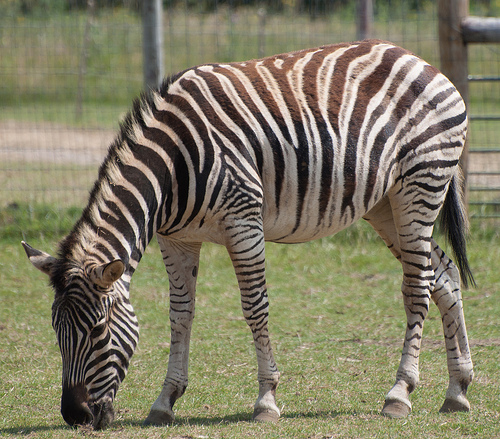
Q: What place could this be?
A: It is a zoo.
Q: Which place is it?
A: It is a zoo.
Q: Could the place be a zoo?
A: Yes, it is a zoo.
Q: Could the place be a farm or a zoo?
A: It is a zoo.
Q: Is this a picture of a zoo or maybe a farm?
A: It is showing a zoo.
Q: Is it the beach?
A: No, it is the zoo.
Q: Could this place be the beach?
A: No, it is the zoo.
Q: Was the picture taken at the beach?
A: No, the picture was taken in the zoo.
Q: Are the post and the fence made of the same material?
A: No, the post is made of wood and the fence is made of metal.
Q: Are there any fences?
A: Yes, there is a fence.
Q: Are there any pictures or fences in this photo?
A: Yes, there is a fence.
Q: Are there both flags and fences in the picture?
A: No, there is a fence but no flags.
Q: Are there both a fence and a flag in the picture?
A: No, there is a fence but no flags.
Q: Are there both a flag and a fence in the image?
A: No, there is a fence but no flags.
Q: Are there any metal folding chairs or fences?
A: Yes, there is a metal fence.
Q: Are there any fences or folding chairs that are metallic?
A: Yes, the fence is metallic.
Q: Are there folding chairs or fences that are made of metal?
A: Yes, the fence is made of metal.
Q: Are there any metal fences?
A: Yes, there is a metal fence.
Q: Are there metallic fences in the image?
A: Yes, there is a metal fence.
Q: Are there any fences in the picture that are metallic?
A: Yes, there is a fence that is metallic.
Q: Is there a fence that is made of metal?
A: Yes, there is a fence that is made of metal.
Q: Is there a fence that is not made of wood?
A: Yes, there is a fence that is made of metal.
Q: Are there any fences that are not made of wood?
A: Yes, there is a fence that is made of metal.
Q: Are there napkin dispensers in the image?
A: No, there are no napkin dispensers.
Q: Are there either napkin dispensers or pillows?
A: No, there are no napkin dispensers or pillows.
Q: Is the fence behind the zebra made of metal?
A: Yes, the fence is made of metal.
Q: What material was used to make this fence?
A: The fence is made of metal.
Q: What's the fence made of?
A: The fence is made of metal.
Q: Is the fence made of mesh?
A: No, the fence is made of metal.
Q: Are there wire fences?
A: No, there is a fence but it is made of metal.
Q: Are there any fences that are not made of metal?
A: No, there is a fence but it is made of metal.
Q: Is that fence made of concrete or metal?
A: The fence is made of metal.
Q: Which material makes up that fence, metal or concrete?
A: The fence is made of metal.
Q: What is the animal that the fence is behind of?
A: The animal is a zebra.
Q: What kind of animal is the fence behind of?
A: The fence is behind the zebra.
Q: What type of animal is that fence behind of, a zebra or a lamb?
A: The fence is behind a zebra.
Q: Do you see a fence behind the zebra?
A: Yes, there is a fence behind the zebra.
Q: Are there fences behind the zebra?
A: Yes, there is a fence behind the zebra.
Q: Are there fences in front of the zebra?
A: No, the fence is behind the zebra.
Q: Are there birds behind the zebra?
A: No, there is a fence behind the zebra.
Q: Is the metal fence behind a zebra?
A: Yes, the fence is behind a zebra.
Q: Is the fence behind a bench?
A: No, the fence is behind a zebra.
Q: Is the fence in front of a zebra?
A: No, the fence is behind a zebra.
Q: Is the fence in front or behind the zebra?
A: The fence is behind the zebra.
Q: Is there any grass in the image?
A: Yes, there is grass.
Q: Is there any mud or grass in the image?
A: Yes, there is grass.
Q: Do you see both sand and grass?
A: No, there is grass but no sand.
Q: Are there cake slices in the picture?
A: No, there are no cake slices.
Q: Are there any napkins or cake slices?
A: No, there are no cake slices or napkins.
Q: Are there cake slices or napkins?
A: No, there are no cake slices or napkins.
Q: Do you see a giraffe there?
A: No, there are no giraffes.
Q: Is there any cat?
A: No, there are no cats.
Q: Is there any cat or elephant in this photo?
A: No, there are no cats or elephants.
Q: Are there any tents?
A: No, there are no tents.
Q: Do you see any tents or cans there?
A: No, there are no tents or cans.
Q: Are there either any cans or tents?
A: No, there are no tents or cans.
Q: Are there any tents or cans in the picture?
A: No, there are no tents or cans.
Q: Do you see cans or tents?
A: No, there are no tents or cans.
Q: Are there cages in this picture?
A: No, there are no cages.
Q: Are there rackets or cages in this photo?
A: No, there are no cages or rackets.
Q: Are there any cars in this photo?
A: No, there are no cars.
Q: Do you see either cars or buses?
A: No, there are no cars or buses.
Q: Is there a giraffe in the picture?
A: No, there are no giraffes.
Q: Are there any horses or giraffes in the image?
A: No, there are no giraffes or horses.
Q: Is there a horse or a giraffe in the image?
A: No, there are no giraffes or horses.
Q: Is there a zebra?
A: Yes, there is a zebra.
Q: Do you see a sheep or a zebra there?
A: Yes, there is a zebra.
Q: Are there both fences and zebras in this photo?
A: Yes, there are both a zebra and a fence.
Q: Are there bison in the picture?
A: No, there are no bison.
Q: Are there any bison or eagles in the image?
A: No, there are no bison or eagles.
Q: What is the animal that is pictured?
A: The animal is a zebra.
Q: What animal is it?
A: The animal is a zebra.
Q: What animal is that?
A: This is a zebra.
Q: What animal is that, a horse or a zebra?
A: This is a zebra.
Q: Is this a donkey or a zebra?
A: This is a zebra.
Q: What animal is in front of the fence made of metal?
A: The zebra is in front of the fence.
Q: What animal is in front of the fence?
A: The zebra is in front of the fence.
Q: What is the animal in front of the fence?
A: The animal is a zebra.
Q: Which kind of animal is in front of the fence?
A: The animal is a zebra.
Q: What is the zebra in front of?
A: The zebra is in front of the fence.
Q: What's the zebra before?
A: The zebra is in front of the fence.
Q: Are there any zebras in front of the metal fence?
A: Yes, there is a zebra in front of the fence.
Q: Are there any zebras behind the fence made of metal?
A: No, the zebra is in front of the fence.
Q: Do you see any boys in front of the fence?
A: No, there is a zebra in front of the fence.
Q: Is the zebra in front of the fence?
A: Yes, the zebra is in front of the fence.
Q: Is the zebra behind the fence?
A: No, the zebra is in front of the fence.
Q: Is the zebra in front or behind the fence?
A: The zebra is in front of the fence.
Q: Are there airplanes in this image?
A: No, there are no airplanes.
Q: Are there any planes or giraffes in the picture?
A: No, there are no planes or giraffes.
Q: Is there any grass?
A: Yes, there is grass.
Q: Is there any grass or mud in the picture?
A: Yes, there is grass.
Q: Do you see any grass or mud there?
A: Yes, there is grass.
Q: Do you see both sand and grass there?
A: No, there is grass but no sand.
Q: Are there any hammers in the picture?
A: No, there are no hammers.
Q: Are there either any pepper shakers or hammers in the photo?
A: No, there are no hammers or pepper shakers.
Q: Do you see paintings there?
A: No, there are no paintings.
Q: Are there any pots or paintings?
A: No, there are no paintings or pots.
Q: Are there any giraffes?
A: No, there are no giraffes.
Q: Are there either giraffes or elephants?
A: No, there are no giraffes or elephants.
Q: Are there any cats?
A: No, there are no cats.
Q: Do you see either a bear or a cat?
A: No, there are no cats or bears.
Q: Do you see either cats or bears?
A: No, there are no cats or bears.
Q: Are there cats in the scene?
A: No, there are no cats.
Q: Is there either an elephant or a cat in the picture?
A: No, there are no cats or elephants.